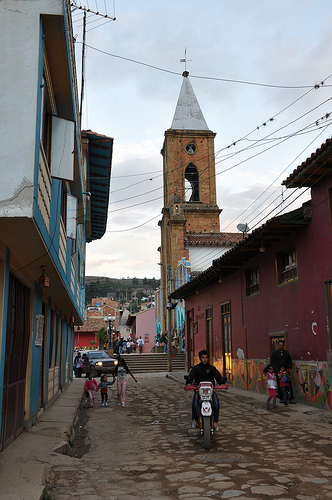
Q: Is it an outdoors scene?
A: Yes, it is outdoors.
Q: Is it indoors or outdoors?
A: It is outdoors.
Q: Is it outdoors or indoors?
A: It is outdoors.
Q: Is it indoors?
A: No, it is outdoors.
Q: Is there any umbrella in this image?
A: No, there are no umbrellas.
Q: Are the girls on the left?
A: Yes, the girls are on the left of the image.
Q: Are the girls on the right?
A: No, the girls are on the left of the image.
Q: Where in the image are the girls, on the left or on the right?
A: The girls are on the left of the image.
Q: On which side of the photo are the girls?
A: The girls are on the left of the image.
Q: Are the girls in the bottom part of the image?
A: Yes, the girls are in the bottom of the image.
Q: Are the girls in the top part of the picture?
A: No, the girls are in the bottom of the image.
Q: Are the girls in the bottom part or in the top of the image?
A: The girls are in the bottom of the image.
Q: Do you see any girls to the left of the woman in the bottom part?
A: Yes, there are girls to the left of the woman.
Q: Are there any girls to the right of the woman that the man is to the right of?
A: No, the girls are to the left of the woman.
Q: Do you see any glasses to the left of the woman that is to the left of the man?
A: No, there are girls to the left of the woman.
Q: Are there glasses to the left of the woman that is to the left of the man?
A: No, there are girls to the left of the woman.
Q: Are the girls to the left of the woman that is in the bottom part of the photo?
A: Yes, the girls are to the left of the woman.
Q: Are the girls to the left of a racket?
A: No, the girls are to the left of the woman.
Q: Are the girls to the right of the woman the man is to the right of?
A: No, the girls are to the left of the woman.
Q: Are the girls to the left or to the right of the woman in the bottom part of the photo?
A: The girls are to the left of the woman.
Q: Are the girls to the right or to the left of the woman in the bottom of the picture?
A: The girls are to the left of the woman.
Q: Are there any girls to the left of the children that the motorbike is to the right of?
A: Yes, there are girls to the left of the children.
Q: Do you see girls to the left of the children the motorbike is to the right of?
A: Yes, there are girls to the left of the children.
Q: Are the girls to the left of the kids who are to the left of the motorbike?
A: Yes, the girls are to the left of the kids.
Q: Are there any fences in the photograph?
A: No, there are no fences.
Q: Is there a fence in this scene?
A: No, there are no fences.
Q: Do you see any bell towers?
A: Yes, there is a bell tower.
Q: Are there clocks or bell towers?
A: Yes, there is a bell tower.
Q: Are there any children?
A: Yes, there are children.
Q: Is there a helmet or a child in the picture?
A: Yes, there are children.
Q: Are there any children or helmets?
A: Yes, there are children.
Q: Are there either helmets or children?
A: Yes, there are children.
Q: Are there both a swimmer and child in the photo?
A: No, there are children but no swimmers.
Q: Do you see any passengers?
A: No, there are no passengers.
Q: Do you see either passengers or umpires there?
A: No, there are no passengers or umpires.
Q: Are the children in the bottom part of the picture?
A: Yes, the children are in the bottom of the image.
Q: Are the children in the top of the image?
A: No, the children are in the bottom of the image.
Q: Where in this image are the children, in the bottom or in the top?
A: The children are in the bottom of the image.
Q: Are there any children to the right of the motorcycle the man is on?
A: Yes, there are children to the right of the motorbike.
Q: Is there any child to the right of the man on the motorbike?
A: Yes, there are children to the right of the man.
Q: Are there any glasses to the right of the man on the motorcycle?
A: No, there are children to the right of the man.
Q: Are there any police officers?
A: No, there are no police officers.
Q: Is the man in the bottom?
A: Yes, the man is in the bottom of the image.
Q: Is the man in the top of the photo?
A: No, the man is in the bottom of the image.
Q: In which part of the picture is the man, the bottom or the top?
A: The man is in the bottom of the image.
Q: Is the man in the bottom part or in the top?
A: The man is in the bottom of the image.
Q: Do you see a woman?
A: Yes, there is a woman.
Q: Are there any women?
A: Yes, there is a woman.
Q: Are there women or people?
A: Yes, there is a woman.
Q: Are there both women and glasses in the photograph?
A: No, there is a woman but no glasses.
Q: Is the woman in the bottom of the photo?
A: Yes, the woman is in the bottom of the image.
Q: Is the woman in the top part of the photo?
A: No, the woman is in the bottom of the image.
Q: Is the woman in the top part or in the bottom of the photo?
A: The woman is in the bottom of the image.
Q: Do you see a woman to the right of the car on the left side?
A: Yes, there is a woman to the right of the car.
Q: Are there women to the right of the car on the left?
A: Yes, there is a woman to the right of the car.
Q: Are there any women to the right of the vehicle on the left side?
A: Yes, there is a woman to the right of the car.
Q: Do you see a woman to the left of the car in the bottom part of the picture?
A: No, the woman is to the right of the car.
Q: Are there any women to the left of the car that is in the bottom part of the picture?
A: No, the woman is to the right of the car.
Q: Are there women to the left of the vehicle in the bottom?
A: No, the woman is to the right of the car.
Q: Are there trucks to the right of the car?
A: No, there is a woman to the right of the car.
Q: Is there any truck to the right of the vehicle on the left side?
A: No, there is a woman to the right of the car.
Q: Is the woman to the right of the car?
A: Yes, the woman is to the right of the car.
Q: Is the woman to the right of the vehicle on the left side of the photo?
A: Yes, the woman is to the right of the car.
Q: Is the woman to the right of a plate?
A: No, the woman is to the right of the car.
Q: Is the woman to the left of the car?
A: No, the woman is to the right of the car.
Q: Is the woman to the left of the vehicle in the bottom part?
A: No, the woman is to the right of the car.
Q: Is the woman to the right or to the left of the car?
A: The woman is to the right of the car.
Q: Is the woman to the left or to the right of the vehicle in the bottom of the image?
A: The woman is to the right of the car.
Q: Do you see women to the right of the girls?
A: Yes, there is a woman to the right of the girls.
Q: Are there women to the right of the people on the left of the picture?
A: Yes, there is a woman to the right of the girls.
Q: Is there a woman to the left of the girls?
A: No, the woman is to the right of the girls.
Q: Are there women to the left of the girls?
A: No, the woman is to the right of the girls.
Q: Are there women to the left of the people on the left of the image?
A: No, the woman is to the right of the girls.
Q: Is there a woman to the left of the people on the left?
A: No, the woman is to the right of the girls.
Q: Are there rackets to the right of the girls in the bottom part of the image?
A: No, there is a woman to the right of the girls.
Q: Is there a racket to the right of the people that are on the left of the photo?
A: No, there is a woman to the right of the girls.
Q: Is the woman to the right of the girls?
A: Yes, the woman is to the right of the girls.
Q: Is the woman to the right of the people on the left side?
A: Yes, the woman is to the right of the girls.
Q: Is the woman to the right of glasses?
A: No, the woman is to the right of the girls.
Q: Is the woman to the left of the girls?
A: No, the woman is to the right of the girls.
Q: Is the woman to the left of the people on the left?
A: No, the woman is to the right of the girls.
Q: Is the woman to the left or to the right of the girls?
A: The woman is to the right of the girls.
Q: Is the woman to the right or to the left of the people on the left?
A: The woman is to the right of the girls.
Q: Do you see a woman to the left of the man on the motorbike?
A: Yes, there is a woman to the left of the man.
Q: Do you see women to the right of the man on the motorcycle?
A: No, the woman is to the left of the man.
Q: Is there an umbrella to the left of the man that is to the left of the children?
A: No, there is a woman to the left of the man.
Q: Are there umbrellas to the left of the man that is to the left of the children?
A: No, there is a woman to the left of the man.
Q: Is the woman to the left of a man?
A: Yes, the woman is to the left of a man.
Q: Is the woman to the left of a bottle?
A: No, the woman is to the left of a man.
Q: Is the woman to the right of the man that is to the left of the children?
A: No, the woman is to the left of the man.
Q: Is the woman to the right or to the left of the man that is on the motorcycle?
A: The woman is to the left of the man.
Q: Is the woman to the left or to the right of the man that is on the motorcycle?
A: The woman is to the left of the man.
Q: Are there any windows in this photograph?
A: Yes, there are windows.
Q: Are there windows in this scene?
A: Yes, there are windows.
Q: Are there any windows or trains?
A: Yes, there are windows.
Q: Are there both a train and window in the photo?
A: No, there are windows but no trains.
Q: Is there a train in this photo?
A: No, there are no trains.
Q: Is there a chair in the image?
A: No, there are no chairs.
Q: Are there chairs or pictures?
A: No, there are no chairs or pictures.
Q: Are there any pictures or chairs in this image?
A: No, there are no chairs or pictures.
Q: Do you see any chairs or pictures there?
A: No, there are no chairs or pictures.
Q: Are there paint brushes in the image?
A: No, there are no paint brushes.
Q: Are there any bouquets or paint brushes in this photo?
A: No, there are no paint brushes or bouquets.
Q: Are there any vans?
A: No, there are no vans.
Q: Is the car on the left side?
A: Yes, the car is on the left of the image.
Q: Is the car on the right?
A: No, the car is on the left of the image.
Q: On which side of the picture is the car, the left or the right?
A: The car is on the left of the image.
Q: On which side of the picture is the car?
A: The car is on the left of the image.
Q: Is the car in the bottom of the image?
A: Yes, the car is in the bottom of the image.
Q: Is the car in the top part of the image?
A: No, the car is in the bottom of the image.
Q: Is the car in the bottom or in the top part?
A: The car is in the bottom of the image.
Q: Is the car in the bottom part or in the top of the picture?
A: The car is in the bottom of the image.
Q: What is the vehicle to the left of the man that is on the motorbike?
A: The vehicle is a car.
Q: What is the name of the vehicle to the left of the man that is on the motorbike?
A: The vehicle is a car.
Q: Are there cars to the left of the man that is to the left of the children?
A: Yes, there is a car to the left of the man.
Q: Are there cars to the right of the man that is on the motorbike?
A: No, the car is to the left of the man.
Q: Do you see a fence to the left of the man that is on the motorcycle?
A: No, there is a car to the left of the man.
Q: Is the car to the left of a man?
A: Yes, the car is to the left of a man.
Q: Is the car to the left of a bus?
A: No, the car is to the left of a man.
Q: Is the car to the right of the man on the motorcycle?
A: No, the car is to the left of the man.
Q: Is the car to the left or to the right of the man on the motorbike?
A: The car is to the left of the man.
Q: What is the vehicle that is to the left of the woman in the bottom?
A: The vehicle is a car.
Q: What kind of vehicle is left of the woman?
A: The vehicle is a car.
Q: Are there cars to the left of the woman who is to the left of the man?
A: Yes, there is a car to the left of the woman.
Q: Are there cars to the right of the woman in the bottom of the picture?
A: No, the car is to the left of the woman.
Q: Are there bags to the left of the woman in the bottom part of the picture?
A: No, there is a car to the left of the woman.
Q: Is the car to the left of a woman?
A: Yes, the car is to the left of a woman.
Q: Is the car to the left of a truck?
A: No, the car is to the left of a woman.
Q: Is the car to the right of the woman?
A: No, the car is to the left of the woman.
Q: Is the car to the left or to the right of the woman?
A: The car is to the left of the woman.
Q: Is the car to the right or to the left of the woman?
A: The car is to the left of the woman.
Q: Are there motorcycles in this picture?
A: Yes, there is a motorcycle.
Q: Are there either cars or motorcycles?
A: Yes, there is a motorcycle.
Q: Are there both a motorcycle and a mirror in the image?
A: No, there is a motorcycle but no mirrors.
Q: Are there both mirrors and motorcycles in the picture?
A: No, there is a motorcycle but no mirrors.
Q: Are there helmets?
A: No, there are no helmets.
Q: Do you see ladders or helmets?
A: No, there are no helmets or ladders.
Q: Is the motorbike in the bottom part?
A: Yes, the motorbike is in the bottom of the image.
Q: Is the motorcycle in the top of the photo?
A: No, the motorcycle is in the bottom of the image.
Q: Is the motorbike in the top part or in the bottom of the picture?
A: The motorbike is in the bottom of the image.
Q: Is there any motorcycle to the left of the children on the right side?
A: Yes, there is a motorcycle to the left of the children.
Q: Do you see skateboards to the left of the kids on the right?
A: No, there is a motorcycle to the left of the children.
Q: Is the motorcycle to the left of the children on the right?
A: Yes, the motorcycle is to the left of the children.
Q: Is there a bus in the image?
A: No, there are no buses.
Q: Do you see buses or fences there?
A: No, there are no buses or fences.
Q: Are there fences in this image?
A: No, there are no fences.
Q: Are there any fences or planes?
A: No, there are no fences or planes.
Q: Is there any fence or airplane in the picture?
A: No, there are no fences or airplanes.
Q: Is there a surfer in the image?
A: No, there are no surfers.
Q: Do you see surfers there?
A: No, there are no surfers.